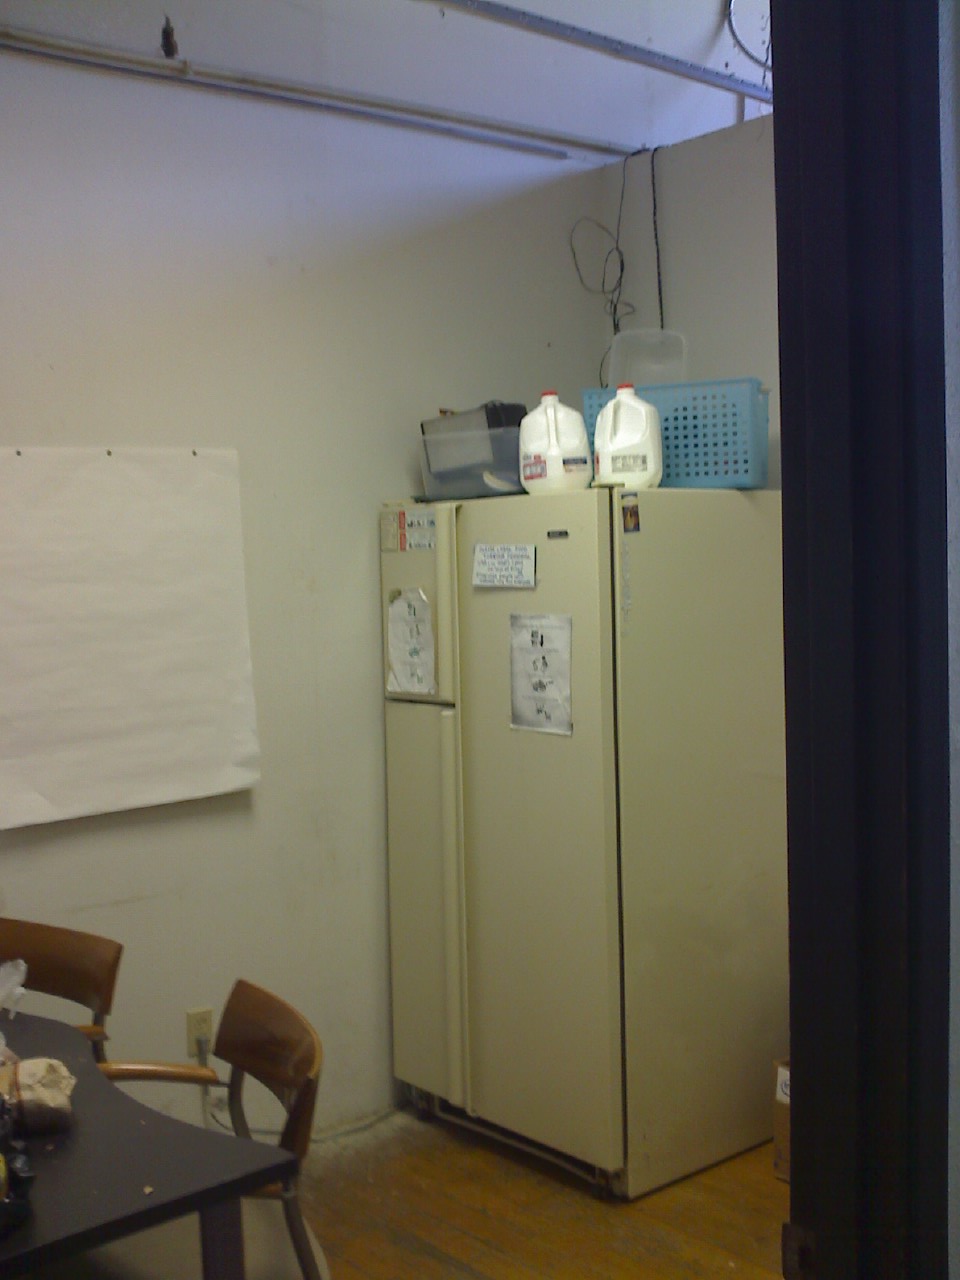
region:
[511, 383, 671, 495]
two one gallon milk containers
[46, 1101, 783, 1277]
wooden floor in a kitchen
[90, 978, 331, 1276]
dining chair in at a black table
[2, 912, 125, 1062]
dining chair at a black table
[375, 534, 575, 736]
papers taped to a refrigerator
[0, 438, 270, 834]
large white pad of paper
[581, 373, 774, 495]
blue plastic bin on a refrigerator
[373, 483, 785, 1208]
light green side by side refrigerator freezer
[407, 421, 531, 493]
clear plastic bin on a refrigerator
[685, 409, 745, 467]
the basket is blue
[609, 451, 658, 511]
the jug is on the fridge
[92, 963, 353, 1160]
the chair is pulled away from the table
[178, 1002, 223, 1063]
the cord is plugged in the outlet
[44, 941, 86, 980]
the chair is brown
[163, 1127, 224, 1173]
the table is black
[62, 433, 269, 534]
the paper is tacked to the wall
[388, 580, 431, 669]
the paper is on the fridge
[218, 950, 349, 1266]
Chair is brown color.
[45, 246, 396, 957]
Wall is white color.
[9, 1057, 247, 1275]
Table is brown color.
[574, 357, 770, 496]
basket is blue color.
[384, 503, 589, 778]
Papers are pasted in the fridge door.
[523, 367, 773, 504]
Basket is in top of fridge.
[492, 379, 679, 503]
THE MILK IS NOT IN THE FRIDGE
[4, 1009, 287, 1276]
THE TABLE IS BLACK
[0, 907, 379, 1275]
THE CHAIRS ARE BROWN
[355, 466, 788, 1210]
THE FRIDGE IS LIGHT BEIGE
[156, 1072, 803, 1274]
THE FLOOR IS DIRTY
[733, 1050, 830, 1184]
THE BOX IS NEXT TO THE FRIDGE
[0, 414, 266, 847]
THE LARGE PAPER IS ON THE WALL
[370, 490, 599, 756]
THE PAPERS ARE ON THE FRIDGE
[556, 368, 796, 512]
THE BASKET IS BLUE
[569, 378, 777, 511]
THE BASKET IS ON TOP OF THE FRIDGE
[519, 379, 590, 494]
Milk jug on top of refrigerator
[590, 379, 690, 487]
Milk jug on top of refrigerator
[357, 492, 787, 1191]
Beige refrigerator in kitchen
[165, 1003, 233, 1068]
Electrical outlet in the wall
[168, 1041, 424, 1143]
Cord plugged into outlet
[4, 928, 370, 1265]
Chairs in the kitchen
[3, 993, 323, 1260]
Black table in the kitchen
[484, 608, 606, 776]
Paper attached to refrigerator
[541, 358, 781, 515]
Blue basket on top of refrigerator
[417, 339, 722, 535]
bottles above the fridge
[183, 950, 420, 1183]
chair in the room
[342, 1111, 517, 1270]
ground under the chair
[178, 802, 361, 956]
wall next to chairs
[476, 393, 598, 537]
a jug on the fridge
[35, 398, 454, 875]
paper on the wall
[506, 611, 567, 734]
a paper on the fridge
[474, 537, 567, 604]
a paper on the fridge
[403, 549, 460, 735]
a paper on the fridge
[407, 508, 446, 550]
a paper on the fridge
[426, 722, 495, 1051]
a handle ont he door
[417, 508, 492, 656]
a handle on the door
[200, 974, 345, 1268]
a chair under the table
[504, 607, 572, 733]
A piece of paper on a fridge.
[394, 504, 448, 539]
A piece of paper on a fridge.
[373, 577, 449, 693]
A piece of paper on a fridge.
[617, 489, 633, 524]
A piece of paper on a fridge.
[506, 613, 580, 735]
A piece of paper on a fridge.